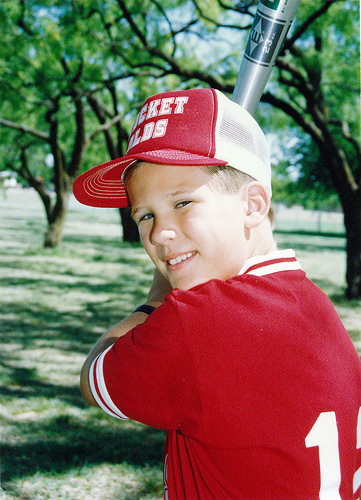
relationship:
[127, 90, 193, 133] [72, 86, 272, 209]
word on ball cap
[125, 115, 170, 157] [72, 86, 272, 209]
word on ball cap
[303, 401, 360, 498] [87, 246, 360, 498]
number on back of shirt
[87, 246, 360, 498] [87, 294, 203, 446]
shirt has sleeve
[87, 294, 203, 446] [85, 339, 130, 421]
sleeve has stripes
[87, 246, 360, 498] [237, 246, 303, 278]
shirt has collar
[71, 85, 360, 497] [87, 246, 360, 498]
boy wearing shirt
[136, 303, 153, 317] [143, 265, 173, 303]
band on hand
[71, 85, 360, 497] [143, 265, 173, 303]
boy has hand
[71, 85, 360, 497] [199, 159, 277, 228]
boy has hair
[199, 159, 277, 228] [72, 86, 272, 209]
hair under ball cap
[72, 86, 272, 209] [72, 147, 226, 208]
ball cap has bill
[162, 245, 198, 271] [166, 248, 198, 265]
smile showing teeth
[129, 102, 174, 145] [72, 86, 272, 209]
writing on ball cap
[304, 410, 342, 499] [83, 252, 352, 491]
number on jersey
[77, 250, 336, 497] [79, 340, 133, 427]
jersey with trim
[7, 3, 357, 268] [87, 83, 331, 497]
trees standing behind player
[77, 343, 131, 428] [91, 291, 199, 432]
stripe on sleeve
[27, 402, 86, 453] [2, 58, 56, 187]
grass beneath trees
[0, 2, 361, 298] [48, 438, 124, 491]
trees on ground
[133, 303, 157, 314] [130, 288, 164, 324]
tape on wrist